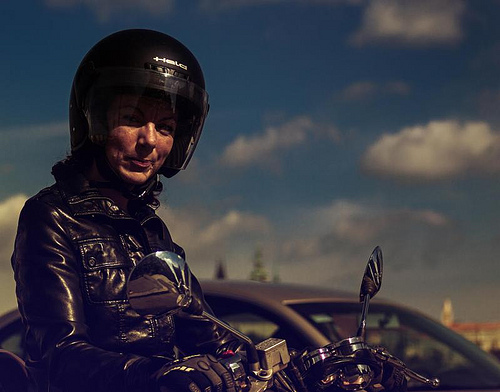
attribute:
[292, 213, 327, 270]
cloud — part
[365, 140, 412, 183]
cloud — part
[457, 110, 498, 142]
cloud — part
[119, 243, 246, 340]
mirror — small, black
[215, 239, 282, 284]
green trees — small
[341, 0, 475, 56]
clouds — white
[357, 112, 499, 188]
clouds — white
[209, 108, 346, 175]
clouds — white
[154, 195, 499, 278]
clouds — white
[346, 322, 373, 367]
handke — part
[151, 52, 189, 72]
logo — white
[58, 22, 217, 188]
helmet — black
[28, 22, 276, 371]
woman — seated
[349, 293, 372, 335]
handle — part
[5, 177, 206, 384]
jacket — black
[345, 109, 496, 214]
cloud — part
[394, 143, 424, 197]
cloud — part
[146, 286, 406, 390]
bike — black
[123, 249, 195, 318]
mirror — small, black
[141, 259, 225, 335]
mirror — part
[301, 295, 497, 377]
windshield — clear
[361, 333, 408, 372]
handle — part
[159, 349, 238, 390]
glove — black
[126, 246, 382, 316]
mirror — small, black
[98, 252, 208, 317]
mirror — small, black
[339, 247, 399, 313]
mirror — small, black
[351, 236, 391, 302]
mirror — small, black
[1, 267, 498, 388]
car — small, grey